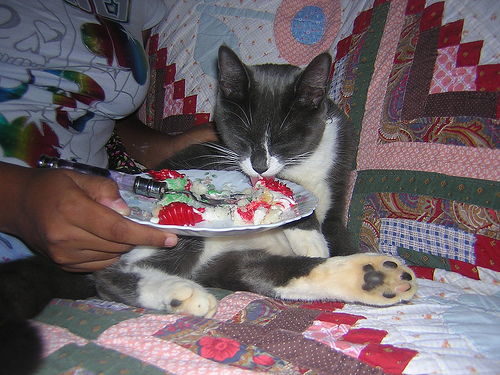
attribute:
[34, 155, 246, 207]
fork — Steel , plastic 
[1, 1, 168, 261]
shirt — print 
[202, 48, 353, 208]
cat — gray, white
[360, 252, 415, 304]
pads — Grey , pink 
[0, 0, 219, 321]
woman — white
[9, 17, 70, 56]
hearts — grey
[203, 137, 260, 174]
whiskers — white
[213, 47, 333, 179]
face — Black , white 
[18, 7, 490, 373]
quilt — Pink, green, red, blue , white 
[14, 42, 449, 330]
cat — gray , white 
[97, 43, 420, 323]
cat — grey, white